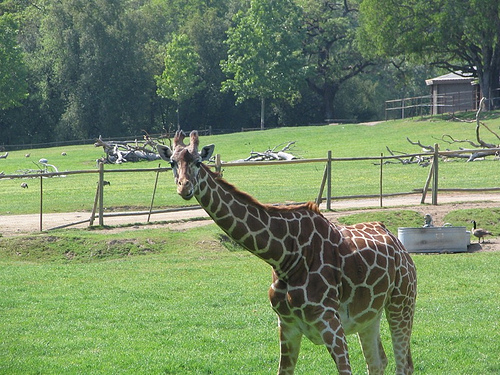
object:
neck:
[195, 161, 313, 272]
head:
[168, 143, 202, 201]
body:
[289, 201, 414, 345]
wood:
[87, 160, 110, 227]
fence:
[0, 144, 496, 235]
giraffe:
[148, 127, 419, 375]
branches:
[94, 129, 171, 165]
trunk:
[371, 97, 500, 166]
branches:
[370, 97, 500, 168]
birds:
[0, 151, 69, 189]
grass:
[0, 111, 500, 374]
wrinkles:
[265, 237, 310, 277]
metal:
[398, 226, 471, 253]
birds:
[422, 213, 434, 228]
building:
[424, 65, 492, 115]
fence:
[384, 84, 499, 118]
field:
[0, 111, 500, 375]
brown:
[273, 223, 283, 234]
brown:
[305, 249, 318, 261]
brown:
[272, 213, 288, 243]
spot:
[208, 176, 261, 256]